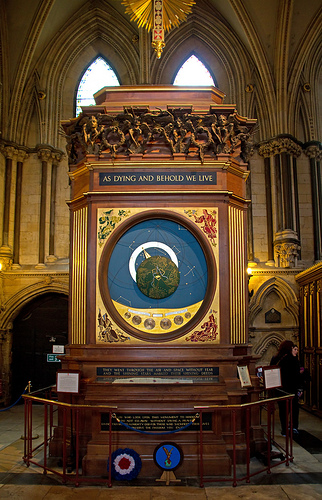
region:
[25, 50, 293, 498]
a monument in a building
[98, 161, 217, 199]
a sign that says as dying behold we live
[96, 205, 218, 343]
a circular shape on a monument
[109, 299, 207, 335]
six circles in a row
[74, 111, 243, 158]
sculptures of people on the top of a monument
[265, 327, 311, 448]
people standing inside an ornate building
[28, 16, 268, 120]
two windows beside each other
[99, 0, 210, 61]
a golden decoration hanging from the ceiling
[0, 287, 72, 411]
a dark hallway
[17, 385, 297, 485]
a barrier around a monument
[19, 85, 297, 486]
wooden monument in a museum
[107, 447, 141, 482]
red, white and blue ribbon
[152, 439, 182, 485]
award for the monument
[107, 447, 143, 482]
award winning ribbon for monument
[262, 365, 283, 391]
information about the monument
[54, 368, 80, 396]
information display about monument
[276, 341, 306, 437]
visitor in the museum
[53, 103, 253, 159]
men engraved on the monument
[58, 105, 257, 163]
statues of men on the monument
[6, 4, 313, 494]
tall monumental statue in a museum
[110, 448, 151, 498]
Red, white, and blue object in front of wood.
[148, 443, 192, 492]
Blue object in front of wood.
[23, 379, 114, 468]
Railing around wood object.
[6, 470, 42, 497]
Floor is brownish tiles.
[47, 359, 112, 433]
White sign on stand.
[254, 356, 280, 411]
White sign on stand.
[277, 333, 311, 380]
Person has dark hair.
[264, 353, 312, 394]
Person wearing dark shirt.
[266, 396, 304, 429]
Person wearing dark pants.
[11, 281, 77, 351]
Ornate archway in background.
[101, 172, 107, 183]
a letter is written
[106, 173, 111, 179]
a letter is written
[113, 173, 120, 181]
a letter is written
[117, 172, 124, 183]
a letter is written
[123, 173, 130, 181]
a letter is written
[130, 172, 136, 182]
a letter is written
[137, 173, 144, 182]
a letter is written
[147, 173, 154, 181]
a letter is written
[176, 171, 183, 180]
a letter is written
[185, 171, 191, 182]
a letter is written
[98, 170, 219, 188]
the writing at the top of the tower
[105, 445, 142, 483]
a ribbon at the bottom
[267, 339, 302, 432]
two women standing in the room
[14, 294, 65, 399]
a large doorway next to the wall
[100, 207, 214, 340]
the clock like device on the side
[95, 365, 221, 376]
some more writing on the side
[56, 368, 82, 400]
a sign behind the barrier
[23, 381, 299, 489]
a barrier around the tower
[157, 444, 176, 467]
a picture of an eagle l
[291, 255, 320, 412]
a display case off to the side